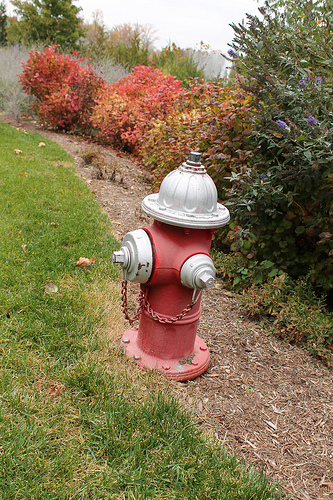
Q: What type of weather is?
A: It is overcast.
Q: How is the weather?
A: It is overcast.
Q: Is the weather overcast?
A: Yes, it is overcast.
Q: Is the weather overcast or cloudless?
A: It is overcast.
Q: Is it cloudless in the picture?
A: No, it is overcast.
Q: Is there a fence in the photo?
A: No, there are no fences.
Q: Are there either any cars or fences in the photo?
A: No, there are no fences or cars.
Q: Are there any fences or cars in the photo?
A: No, there are no fences or cars.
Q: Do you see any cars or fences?
A: No, there are no fences or cars.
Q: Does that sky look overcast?
A: Yes, the sky is overcast.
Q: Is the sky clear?
A: No, the sky is overcast.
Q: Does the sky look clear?
A: No, the sky is overcast.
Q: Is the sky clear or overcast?
A: The sky is overcast.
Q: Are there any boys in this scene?
A: No, there are no boys.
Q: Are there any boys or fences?
A: No, there are no boys or fences.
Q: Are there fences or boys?
A: No, there are no boys or fences.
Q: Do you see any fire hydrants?
A: Yes, there is a fire hydrant.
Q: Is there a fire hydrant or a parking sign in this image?
A: Yes, there is a fire hydrant.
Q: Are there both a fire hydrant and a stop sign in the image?
A: No, there is a fire hydrant but no stop signs.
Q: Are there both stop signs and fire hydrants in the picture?
A: No, there is a fire hydrant but no stop signs.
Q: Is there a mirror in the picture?
A: No, there are no mirrors.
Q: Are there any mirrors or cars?
A: No, there are no mirrors or cars.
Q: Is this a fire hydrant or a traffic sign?
A: This is a fire hydrant.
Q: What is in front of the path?
A: The fire hydrant is in front of the path.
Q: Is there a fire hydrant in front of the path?
A: Yes, there is a fire hydrant in front of the path.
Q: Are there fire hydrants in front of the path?
A: Yes, there is a fire hydrant in front of the path.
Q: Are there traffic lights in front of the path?
A: No, there is a fire hydrant in front of the path.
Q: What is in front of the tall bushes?
A: The hydrant is in front of the bushes.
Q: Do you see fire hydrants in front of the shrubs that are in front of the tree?
A: Yes, there is a fire hydrant in front of the shrubs.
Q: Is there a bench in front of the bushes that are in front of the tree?
A: No, there is a fire hydrant in front of the shrubs.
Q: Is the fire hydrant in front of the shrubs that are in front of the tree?
A: Yes, the fire hydrant is in front of the bushes.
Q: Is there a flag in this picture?
A: No, there are no flags.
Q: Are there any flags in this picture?
A: No, there are no flags.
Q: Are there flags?
A: No, there are no flags.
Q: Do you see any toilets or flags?
A: No, there are no flags or toilets.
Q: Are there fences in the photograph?
A: No, there are no fences.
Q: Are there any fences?
A: No, there are no fences.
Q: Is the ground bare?
A: Yes, the ground is bare.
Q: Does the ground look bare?
A: Yes, the ground is bare.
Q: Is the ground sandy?
A: No, the ground is bare.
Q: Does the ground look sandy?
A: No, the ground is bare.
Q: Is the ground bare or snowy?
A: The ground is bare.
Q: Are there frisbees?
A: No, there are no frisbees.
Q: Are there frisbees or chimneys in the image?
A: No, there are no frisbees or chimneys.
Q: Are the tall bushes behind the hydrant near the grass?
A: Yes, the shrubs are behind the hydrant.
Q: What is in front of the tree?
A: The bushes are in front of the tree.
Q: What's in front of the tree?
A: The bushes are in front of the tree.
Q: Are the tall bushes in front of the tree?
A: Yes, the shrubs are in front of the tree.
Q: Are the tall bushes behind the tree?
A: No, the shrubs are in front of the tree.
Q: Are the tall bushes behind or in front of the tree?
A: The shrubs are in front of the tree.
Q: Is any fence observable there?
A: No, there are no fences.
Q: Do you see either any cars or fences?
A: No, there are no fences or cars.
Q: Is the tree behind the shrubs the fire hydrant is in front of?
A: Yes, the tree is behind the bushes.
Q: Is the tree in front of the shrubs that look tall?
A: No, the tree is behind the bushes.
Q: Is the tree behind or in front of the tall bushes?
A: The tree is behind the bushes.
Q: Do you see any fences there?
A: No, there are no fences.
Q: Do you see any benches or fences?
A: No, there are no fences or benches.